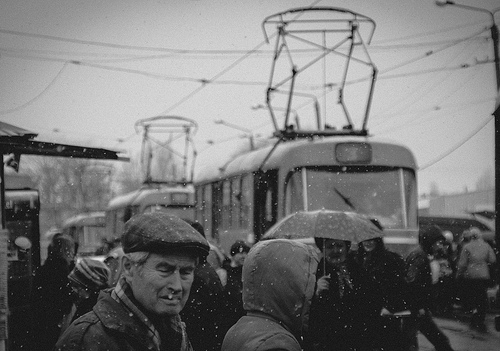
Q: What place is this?
A: It is a station.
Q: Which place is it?
A: It is a station.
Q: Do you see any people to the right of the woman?
A: Yes, there are people to the right of the woman.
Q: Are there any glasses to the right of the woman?
A: No, there are people to the right of the woman.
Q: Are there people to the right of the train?
A: Yes, there are people to the right of the train.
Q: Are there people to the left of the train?
A: No, the people are to the right of the train.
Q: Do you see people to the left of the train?
A: No, the people are to the right of the train.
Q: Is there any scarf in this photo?
A: Yes, there is a scarf.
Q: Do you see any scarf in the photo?
A: Yes, there is a scarf.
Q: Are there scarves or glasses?
A: Yes, there is a scarf.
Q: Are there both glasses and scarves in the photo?
A: No, there is a scarf but no glasses.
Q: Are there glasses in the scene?
A: No, there are no glasses.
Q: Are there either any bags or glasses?
A: No, there are no glasses or bags.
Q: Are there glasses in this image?
A: No, there are no glasses.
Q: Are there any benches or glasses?
A: No, there are no glasses or benches.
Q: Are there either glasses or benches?
A: No, there are no glasses or benches.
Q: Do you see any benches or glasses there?
A: No, there are no glasses or benches.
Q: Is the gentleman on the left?
A: Yes, the gentleman is on the left of the image.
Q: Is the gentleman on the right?
A: No, the gentleman is on the left of the image.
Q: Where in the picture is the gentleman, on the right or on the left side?
A: The gentleman is on the left of the image.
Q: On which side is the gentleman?
A: The gentleman is on the left of the image.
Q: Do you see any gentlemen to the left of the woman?
A: Yes, there is a gentleman to the left of the woman.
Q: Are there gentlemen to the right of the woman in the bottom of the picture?
A: No, the gentleman is to the left of the woman.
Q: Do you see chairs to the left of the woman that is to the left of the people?
A: No, there is a gentleman to the left of the woman.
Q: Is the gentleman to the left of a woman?
A: Yes, the gentleman is to the left of a woman.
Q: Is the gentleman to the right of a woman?
A: No, the gentleman is to the left of a woman.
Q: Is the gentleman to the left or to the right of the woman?
A: The gentleman is to the left of the woman.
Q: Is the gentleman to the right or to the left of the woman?
A: The gentleman is to the left of the woman.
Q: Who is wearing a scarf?
A: The gentleman is wearing a scarf.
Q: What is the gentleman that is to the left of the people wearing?
A: The gentleman is wearing a scarf.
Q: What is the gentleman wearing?
A: The gentleman is wearing a scarf.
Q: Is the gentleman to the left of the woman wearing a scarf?
A: Yes, the gentleman is wearing a scarf.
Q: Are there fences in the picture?
A: No, there are no fences.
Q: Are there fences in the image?
A: No, there are no fences.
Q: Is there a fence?
A: No, there are no fences.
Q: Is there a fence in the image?
A: No, there are no fences.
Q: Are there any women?
A: Yes, there is a woman.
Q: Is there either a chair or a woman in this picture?
A: Yes, there is a woman.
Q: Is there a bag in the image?
A: No, there are no bags.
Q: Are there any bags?
A: No, there are no bags.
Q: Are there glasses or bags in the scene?
A: No, there are no bags or glasses.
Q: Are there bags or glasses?
A: No, there are no bags or glasses.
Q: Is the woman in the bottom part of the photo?
A: Yes, the woman is in the bottom of the image.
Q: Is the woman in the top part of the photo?
A: No, the woman is in the bottom of the image.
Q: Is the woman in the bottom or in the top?
A: The woman is in the bottom of the image.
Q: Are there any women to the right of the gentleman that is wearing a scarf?
A: Yes, there is a woman to the right of the gentleman.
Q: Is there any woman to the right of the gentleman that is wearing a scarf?
A: Yes, there is a woman to the right of the gentleman.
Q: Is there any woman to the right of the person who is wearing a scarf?
A: Yes, there is a woman to the right of the gentleman.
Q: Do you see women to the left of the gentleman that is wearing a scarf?
A: No, the woman is to the right of the gentleman.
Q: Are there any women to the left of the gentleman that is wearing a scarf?
A: No, the woman is to the right of the gentleman.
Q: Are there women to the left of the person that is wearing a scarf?
A: No, the woman is to the right of the gentleman.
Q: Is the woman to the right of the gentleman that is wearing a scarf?
A: Yes, the woman is to the right of the gentleman.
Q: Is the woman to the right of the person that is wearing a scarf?
A: Yes, the woman is to the right of the gentleman.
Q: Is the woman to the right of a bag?
A: No, the woman is to the right of the gentleman.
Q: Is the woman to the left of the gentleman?
A: No, the woman is to the right of the gentleman.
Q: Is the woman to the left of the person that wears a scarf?
A: No, the woman is to the right of the gentleman.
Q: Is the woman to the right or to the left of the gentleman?
A: The woman is to the right of the gentleman.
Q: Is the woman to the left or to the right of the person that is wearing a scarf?
A: The woman is to the right of the gentleman.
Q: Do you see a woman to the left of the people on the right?
A: Yes, there is a woman to the left of the people.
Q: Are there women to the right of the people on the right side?
A: No, the woman is to the left of the people.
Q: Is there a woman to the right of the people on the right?
A: No, the woman is to the left of the people.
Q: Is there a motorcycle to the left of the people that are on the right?
A: No, there is a woman to the left of the people.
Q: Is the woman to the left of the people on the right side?
A: Yes, the woman is to the left of the people.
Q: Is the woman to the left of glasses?
A: No, the woman is to the left of the people.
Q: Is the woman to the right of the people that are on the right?
A: No, the woman is to the left of the people.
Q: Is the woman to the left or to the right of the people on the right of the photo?
A: The woman is to the left of the people.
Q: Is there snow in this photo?
A: Yes, there is snow.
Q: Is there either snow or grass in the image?
A: Yes, there is snow.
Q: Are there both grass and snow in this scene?
A: No, there is snow but no grass.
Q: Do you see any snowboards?
A: No, there are no snowboards.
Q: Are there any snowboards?
A: No, there are no snowboards.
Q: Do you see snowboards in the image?
A: No, there are no snowboards.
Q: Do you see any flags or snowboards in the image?
A: No, there are no snowboards or flags.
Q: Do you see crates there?
A: No, there are no crates.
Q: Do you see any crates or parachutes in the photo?
A: No, there are no crates or parachutes.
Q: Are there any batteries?
A: No, there are no batteries.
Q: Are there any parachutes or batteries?
A: No, there are no batteries or parachutes.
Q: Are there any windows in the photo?
A: Yes, there is a window.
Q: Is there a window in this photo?
A: Yes, there is a window.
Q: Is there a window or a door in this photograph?
A: Yes, there is a window.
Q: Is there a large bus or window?
A: Yes, there is a large window.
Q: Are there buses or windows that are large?
A: Yes, the window is large.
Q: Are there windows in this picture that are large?
A: Yes, there is a large window.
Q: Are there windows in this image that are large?
A: Yes, there is a window that is large.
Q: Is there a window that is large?
A: Yes, there is a window that is large.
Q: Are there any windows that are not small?
A: Yes, there is a large window.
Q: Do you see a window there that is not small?
A: Yes, there is a large window.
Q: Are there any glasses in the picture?
A: No, there are no glasses.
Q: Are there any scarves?
A: Yes, there is a scarf.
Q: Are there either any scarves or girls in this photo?
A: Yes, there is a scarf.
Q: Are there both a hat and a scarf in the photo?
A: Yes, there are both a scarf and a hat.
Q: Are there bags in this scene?
A: No, there are no bags.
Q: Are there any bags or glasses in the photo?
A: No, there are no bags or glasses.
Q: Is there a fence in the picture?
A: No, there are no fences.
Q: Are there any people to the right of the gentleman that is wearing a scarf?
A: Yes, there are people to the right of the gentleman.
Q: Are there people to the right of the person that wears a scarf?
A: Yes, there are people to the right of the gentleman.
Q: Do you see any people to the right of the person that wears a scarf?
A: Yes, there are people to the right of the gentleman.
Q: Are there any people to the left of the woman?
A: Yes, there are people to the left of the woman.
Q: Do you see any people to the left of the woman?
A: Yes, there are people to the left of the woman.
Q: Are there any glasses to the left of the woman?
A: No, there are people to the left of the woman.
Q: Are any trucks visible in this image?
A: No, there are no trucks.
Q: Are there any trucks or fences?
A: No, there are no trucks or fences.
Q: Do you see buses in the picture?
A: Yes, there is a bus.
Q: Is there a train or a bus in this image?
A: Yes, there is a bus.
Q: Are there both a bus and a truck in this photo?
A: No, there is a bus but no trucks.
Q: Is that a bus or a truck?
A: That is a bus.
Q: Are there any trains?
A: Yes, there is a train.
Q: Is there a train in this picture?
A: Yes, there is a train.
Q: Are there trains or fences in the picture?
A: Yes, there is a train.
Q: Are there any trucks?
A: No, there are no trucks.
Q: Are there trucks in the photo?
A: No, there are no trucks.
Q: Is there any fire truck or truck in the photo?
A: No, there are no trucks or fire trucks.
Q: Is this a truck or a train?
A: This is a train.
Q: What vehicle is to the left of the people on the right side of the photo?
A: The vehicle is a train.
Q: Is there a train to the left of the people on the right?
A: Yes, there is a train to the left of the people.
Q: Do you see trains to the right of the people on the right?
A: No, the train is to the left of the people.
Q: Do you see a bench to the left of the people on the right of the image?
A: No, there is a train to the left of the people.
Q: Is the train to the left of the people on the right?
A: Yes, the train is to the left of the people.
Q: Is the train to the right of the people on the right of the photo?
A: No, the train is to the left of the people.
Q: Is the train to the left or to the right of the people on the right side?
A: The train is to the left of the people.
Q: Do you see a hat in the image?
A: Yes, there is a hat.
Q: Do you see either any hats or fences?
A: Yes, there is a hat.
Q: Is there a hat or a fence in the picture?
A: Yes, there is a hat.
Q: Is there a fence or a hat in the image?
A: Yes, there is a hat.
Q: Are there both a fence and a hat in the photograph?
A: No, there is a hat but no fences.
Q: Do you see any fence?
A: No, there are no fences.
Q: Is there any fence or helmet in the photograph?
A: No, there are no fences or helmets.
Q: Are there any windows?
A: Yes, there is a window.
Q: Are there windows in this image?
A: Yes, there is a window.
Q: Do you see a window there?
A: Yes, there is a window.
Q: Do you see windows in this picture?
A: Yes, there is a window.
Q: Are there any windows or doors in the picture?
A: Yes, there is a window.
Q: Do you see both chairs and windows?
A: No, there is a window but no chairs.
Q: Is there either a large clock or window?
A: Yes, there is a large window.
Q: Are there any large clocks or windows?
A: Yes, there is a large window.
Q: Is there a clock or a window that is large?
A: Yes, the window is large.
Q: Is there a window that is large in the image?
A: Yes, there is a large window.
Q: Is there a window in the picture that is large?
A: Yes, there is a window that is large.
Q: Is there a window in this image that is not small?
A: Yes, there is a large window.